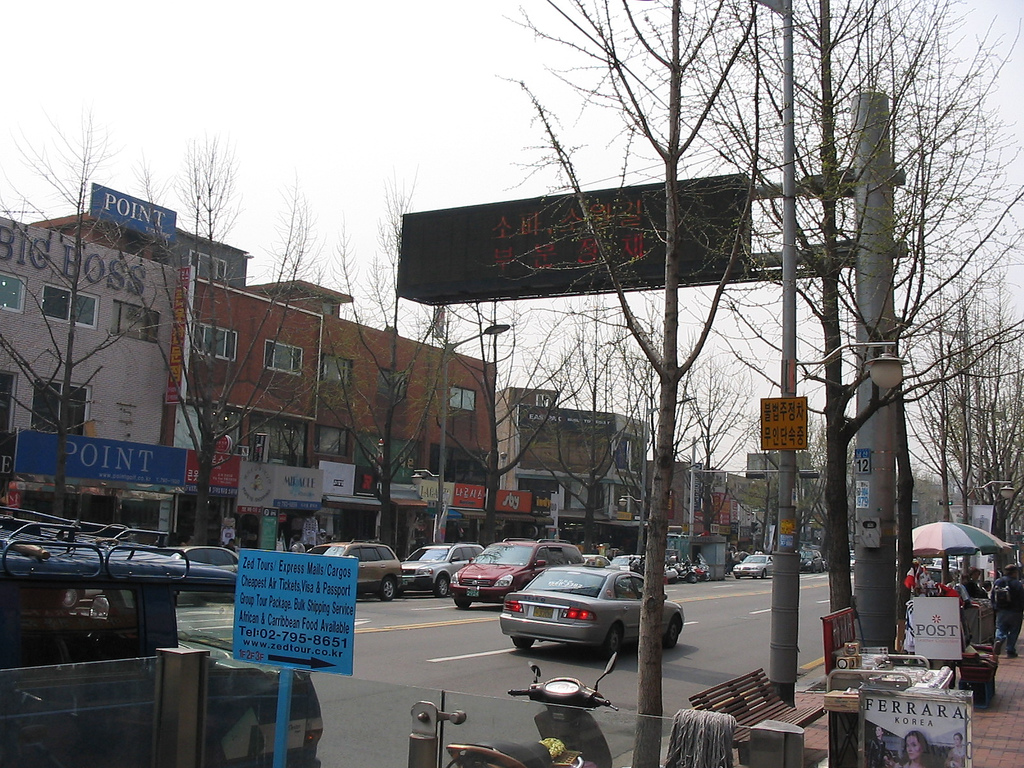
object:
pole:
[769, 16, 801, 686]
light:
[759, 0, 801, 708]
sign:
[761, 397, 807, 449]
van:
[401, 544, 485, 598]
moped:
[408, 652, 619, 768]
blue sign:
[14, 429, 187, 487]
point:
[66, 441, 153, 472]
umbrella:
[896, 522, 1015, 557]